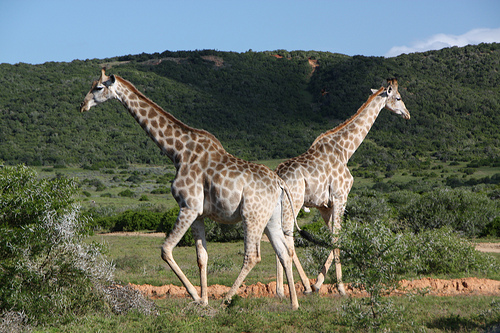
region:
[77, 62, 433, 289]
two giraffes walking in opposite directions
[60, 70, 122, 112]
the head of a tall giraffe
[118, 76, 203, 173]
the neck of a tall giraffe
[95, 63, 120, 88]
the ear of a tall giraffe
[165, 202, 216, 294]
the front legs of a tall giraffe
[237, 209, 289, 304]
the hind legs of a tall giraffe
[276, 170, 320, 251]
the tail of a tall giraffe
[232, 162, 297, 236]
the hind end of a tall giraffe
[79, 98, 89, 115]
the lips of a tall giraffe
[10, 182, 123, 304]
small shrubs of some trees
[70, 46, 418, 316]
the giraffes walking opposite directions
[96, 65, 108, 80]
the horns on the head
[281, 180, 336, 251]
the tail of the giraffe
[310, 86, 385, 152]
the hair on the back of the neck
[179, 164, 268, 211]
the borwn patches on the giraffe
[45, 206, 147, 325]
the grey brush in the bushes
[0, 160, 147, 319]
the bushes by the giraffe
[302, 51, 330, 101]
the dirt path on the hill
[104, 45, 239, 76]
the clearing on the hill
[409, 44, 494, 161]
the green trees on the hillside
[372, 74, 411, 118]
the head of a giraffe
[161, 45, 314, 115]
a green hill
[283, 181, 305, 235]
the tail of a giraffe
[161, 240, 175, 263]
the knee of a giraffe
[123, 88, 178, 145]
the neck of a giraffe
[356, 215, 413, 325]
a tree with thorns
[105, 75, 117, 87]
the ear of a giraffe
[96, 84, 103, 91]
the eye of a giraffe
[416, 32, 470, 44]
white clouds in the distant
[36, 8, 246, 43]
blue skies in the distant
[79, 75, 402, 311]
the two giraffes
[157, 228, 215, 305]
legs on the giraffe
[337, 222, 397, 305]
a green bush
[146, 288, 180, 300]
brown dirt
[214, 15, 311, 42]
the sky is clear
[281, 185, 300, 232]
the giraffes tail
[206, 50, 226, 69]
dirt in the mountain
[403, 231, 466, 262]
the leaves are green on the plant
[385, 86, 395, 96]
the giraffes ear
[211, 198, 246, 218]
the stomach of the giraffe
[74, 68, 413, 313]
Two large giraffes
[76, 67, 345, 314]
Big giraffe moving towards the left.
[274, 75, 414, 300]
Smaller giraffe moving towards the right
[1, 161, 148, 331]
Green bush in the foreground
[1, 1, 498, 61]
One little white cloud in a bright blue sky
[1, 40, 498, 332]
Green hillside behind two giraffes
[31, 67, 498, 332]
Two giraffes walking in the green grass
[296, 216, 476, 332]
Small green bush in front of small giraffe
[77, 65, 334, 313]
giraffe has a bent leg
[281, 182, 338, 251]
the tail of a giraffe